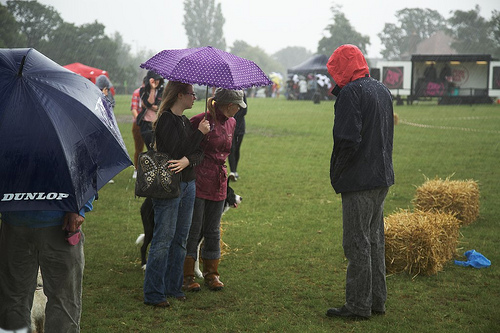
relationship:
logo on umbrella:
[3, 190, 69, 204] [2, 47, 129, 214]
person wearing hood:
[326, 43, 395, 321] [325, 44, 370, 87]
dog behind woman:
[223, 185, 242, 218] [181, 88, 248, 292]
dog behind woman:
[223, 185, 242, 218] [144, 80, 209, 307]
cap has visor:
[216, 88, 248, 110] [238, 102, 247, 109]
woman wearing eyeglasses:
[144, 80, 209, 307] [179, 90, 196, 97]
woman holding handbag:
[144, 80, 209, 307] [134, 109, 191, 199]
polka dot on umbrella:
[184, 77, 186, 81] [140, 47, 275, 131]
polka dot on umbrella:
[189, 64, 193, 69] [140, 47, 275, 131]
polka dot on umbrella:
[223, 76, 227, 80] [140, 47, 275, 131]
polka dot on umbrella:
[208, 66, 213, 70] [140, 47, 275, 131]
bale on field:
[383, 211, 464, 277] [80, 93, 499, 331]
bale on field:
[414, 179, 482, 224] [80, 93, 499, 331]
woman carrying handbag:
[144, 80, 209, 307] [134, 109, 191, 199]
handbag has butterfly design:
[134, 109, 191, 199] [139, 155, 178, 194]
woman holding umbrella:
[144, 80, 209, 307] [140, 47, 275, 131]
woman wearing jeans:
[144, 80, 209, 307] [145, 181, 193, 303]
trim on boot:
[198, 250, 225, 259] [200, 250, 224, 290]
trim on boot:
[184, 252, 197, 259] [182, 253, 200, 291]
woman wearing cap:
[181, 88, 248, 292] [216, 88, 248, 110]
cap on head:
[216, 88, 248, 110] [215, 87, 247, 120]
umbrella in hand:
[140, 47, 275, 131] [198, 117, 212, 134]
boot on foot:
[182, 253, 200, 291] [180, 280, 202, 293]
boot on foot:
[200, 250, 224, 290] [205, 278, 226, 289]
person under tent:
[297, 78, 310, 101] [288, 53, 338, 101]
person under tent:
[306, 74, 317, 101] [288, 53, 338, 101]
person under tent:
[290, 75, 299, 99] [288, 53, 338, 101]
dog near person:
[223, 185, 242, 218] [326, 43, 395, 321]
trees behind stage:
[377, 4, 498, 60] [408, 54, 492, 103]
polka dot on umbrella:
[197, 71, 201, 75] [140, 47, 275, 131]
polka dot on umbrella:
[208, 79, 213, 84] [140, 47, 275, 131]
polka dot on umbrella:
[234, 79, 239, 84] [140, 47, 275, 131]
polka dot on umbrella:
[223, 68, 227, 73] [140, 47, 275, 131]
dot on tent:
[89, 70, 95, 75] [61, 62, 108, 86]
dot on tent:
[102, 70, 106, 74] [61, 62, 108, 86]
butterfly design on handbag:
[139, 155, 178, 194] [134, 109, 191, 199]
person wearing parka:
[326, 43, 395, 321] [328, 78, 395, 194]